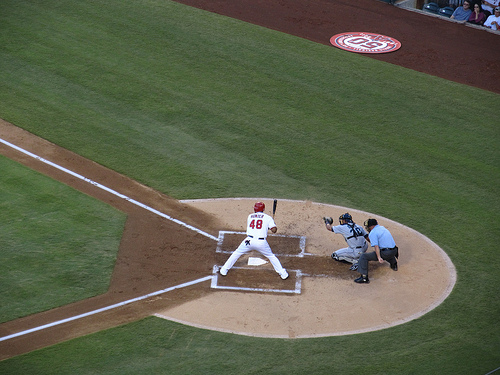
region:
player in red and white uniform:
[191, 165, 319, 306]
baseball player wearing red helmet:
[221, 175, 292, 233]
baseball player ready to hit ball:
[214, 185, 318, 340]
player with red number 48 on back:
[230, 178, 288, 305]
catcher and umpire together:
[311, 194, 395, 294]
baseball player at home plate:
[181, 145, 353, 337]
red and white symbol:
[330, 4, 424, 84]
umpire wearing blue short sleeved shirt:
[354, 188, 435, 305]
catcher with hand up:
[302, 191, 387, 289]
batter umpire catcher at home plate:
[175, 175, 427, 299]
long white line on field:
[77, 300, 153, 326]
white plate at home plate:
[243, 252, 275, 272]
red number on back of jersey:
[238, 209, 275, 235]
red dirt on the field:
[135, 233, 188, 268]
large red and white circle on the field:
[300, 15, 438, 72]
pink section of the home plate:
[243, 302, 347, 321]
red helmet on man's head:
[243, 197, 295, 216]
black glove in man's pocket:
[235, 230, 258, 256]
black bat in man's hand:
[270, 194, 287, 235]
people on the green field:
[216, 175, 438, 328]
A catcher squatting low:
[319, 210, 364, 258]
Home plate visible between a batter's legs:
[239, 247, 265, 274]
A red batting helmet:
[254, 199, 264, 213]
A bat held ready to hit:
[261, 191, 287, 234]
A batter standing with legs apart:
[224, 200, 290, 277]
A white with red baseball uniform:
[218, 206, 288, 279]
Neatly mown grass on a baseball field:
[79, 54, 403, 151]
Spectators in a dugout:
[430, 2, 497, 30]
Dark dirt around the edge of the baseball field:
[396, 43, 487, 68]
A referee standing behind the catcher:
[361, 213, 405, 281]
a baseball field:
[19, 11, 490, 354]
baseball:
[13, 32, 498, 356]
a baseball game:
[35, 52, 484, 356]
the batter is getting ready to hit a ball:
[223, 187, 294, 292]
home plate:
[248, 254, 268, 267]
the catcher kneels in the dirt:
[315, 202, 368, 272]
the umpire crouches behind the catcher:
[356, 215, 403, 285]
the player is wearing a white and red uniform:
[220, 188, 297, 293]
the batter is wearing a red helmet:
[225, 189, 295, 285]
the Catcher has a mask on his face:
[323, 211, 368, 268]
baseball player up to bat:
[200, 194, 295, 301]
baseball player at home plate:
[210, 184, 295, 298]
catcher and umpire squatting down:
[312, 197, 430, 302]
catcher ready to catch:
[318, 212, 372, 292]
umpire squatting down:
[362, 214, 404, 284]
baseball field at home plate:
[25, 58, 482, 343]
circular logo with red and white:
[325, 15, 420, 82]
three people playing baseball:
[224, 181, 412, 293]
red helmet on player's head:
[242, 195, 267, 213]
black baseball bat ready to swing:
[268, 190, 285, 224]